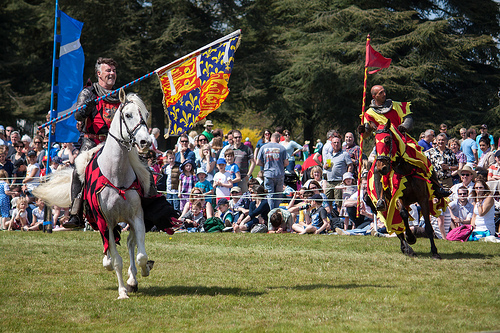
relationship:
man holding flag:
[82, 59, 123, 142] [41, 29, 243, 131]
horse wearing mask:
[365, 110, 442, 259] [365, 117, 402, 166]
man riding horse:
[82, 59, 123, 142] [51, 92, 160, 299]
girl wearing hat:
[208, 154, 233, 203] [216, 156, 227, 169]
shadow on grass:
[149, 269, 268, 314] [9, 219, 498, 332]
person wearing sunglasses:
[228, 126, 248, 175] [231, 135, 244, 141]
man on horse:
[82, 59, 123, 142] [51, 92, 160, 299]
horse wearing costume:
[365, 110, 442, 259] [358, 101, 435, 173]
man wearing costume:
[360, 88, 419, 169] [361, 103, 429, 170]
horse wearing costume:
[51, 92, 160, 299] [74, 154, 180, 242]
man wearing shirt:
[259, 129, 284, 192] [264, 147, 285, 174]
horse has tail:
[51, 92, 160, 299] [34, 170, 78, 201]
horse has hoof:
[51, 92, 160, 299] [123, 278, 139, 293]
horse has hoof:
[51, 92, 160, 299] [145, 259, 157, 268]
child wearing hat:
[343, 169, 373, 230] [339, 172, 357, 186]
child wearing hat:
[222, 175, 249, 223] [229, 182, 246, 200]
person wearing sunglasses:
[328, 135, 354, 185] [231, 135, 244, 141]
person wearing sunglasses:
[456, 162, 475, 201] [462, 172, 468, 180]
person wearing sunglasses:
[451, 187, 476, 227] [457, 194, 471, 200]